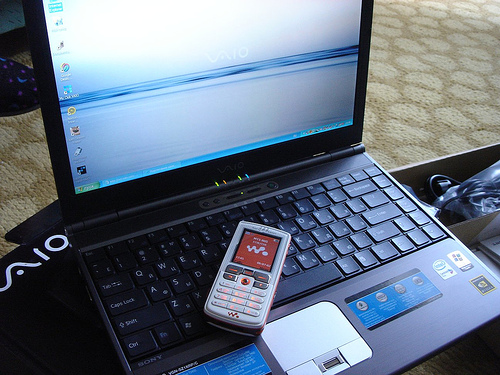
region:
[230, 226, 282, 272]
red screen on the cell phone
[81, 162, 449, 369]
keyboard on the laptop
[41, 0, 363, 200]
screen on the lap top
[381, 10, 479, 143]
patterned carpet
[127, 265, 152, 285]
the letter Q on the keyboard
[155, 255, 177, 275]
the letter W on the keyboard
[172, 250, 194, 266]
the letter E on the keyboard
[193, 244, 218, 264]
the letter R on the keyboard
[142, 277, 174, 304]
the letter A on the keyboard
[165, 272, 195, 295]
the letter S on the keyboard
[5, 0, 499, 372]
black laptop on it's wallpaper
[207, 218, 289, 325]
a silver cell phone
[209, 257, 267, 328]
cell phone dial pad with back light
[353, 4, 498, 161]
biege on beige patterned carpet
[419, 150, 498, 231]
video game controller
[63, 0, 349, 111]
sandy beach with blue water to the horizon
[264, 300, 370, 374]
a touch pad under the keyboard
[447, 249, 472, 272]
a windows logo sticker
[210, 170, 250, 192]
control lights on the screen panel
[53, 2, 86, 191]
most used icons on the start page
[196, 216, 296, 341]
A cellphone sitting on the laptop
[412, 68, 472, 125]
Part of the carpet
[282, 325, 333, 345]
Part of the touchpad mouse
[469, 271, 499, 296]
A blue sticker on the laptop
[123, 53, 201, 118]
Part of the laptop's screen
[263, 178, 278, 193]
The power button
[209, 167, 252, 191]
Blue, red, and green lights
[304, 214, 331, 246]
Part of the keyboard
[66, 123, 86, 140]
A shortcut on the screen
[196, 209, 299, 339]
A cell phone sitting on a keyboard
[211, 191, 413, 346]
The keyboard is on a laptop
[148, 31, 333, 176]
The desktop of the lap top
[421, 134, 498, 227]
More laptop parts in a box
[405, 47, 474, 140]
The carpet is two tone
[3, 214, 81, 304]
Packaging from the laptop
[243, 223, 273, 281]
The cell phone screen is red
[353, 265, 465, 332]
Stickers on the laptop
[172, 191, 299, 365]
a phone on the keyboard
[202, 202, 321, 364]
a phone on the keyboard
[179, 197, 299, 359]
a phone on the keyboard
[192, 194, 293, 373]
a phone on the keyboard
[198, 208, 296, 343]
the phone is white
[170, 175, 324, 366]
the phone is white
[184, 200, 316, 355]
the phone is white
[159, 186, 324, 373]
the phone is white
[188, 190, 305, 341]
the phone is white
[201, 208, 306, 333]
cellphone on the laptop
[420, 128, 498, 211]
wires near the laptop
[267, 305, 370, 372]
mouse pad on the laptop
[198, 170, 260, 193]
lights on the laptop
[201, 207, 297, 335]
cellphone is silver and red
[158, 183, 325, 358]
phone on the laptop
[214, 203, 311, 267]
top of the phone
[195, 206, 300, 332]
red logo on the phone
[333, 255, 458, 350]
sticker on the laptop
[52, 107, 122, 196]
logos on the screen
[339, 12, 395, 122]
edge of the laptop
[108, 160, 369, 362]
phone sitting on the keys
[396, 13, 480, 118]
floor near the laptop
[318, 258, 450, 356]
blue and black sticker